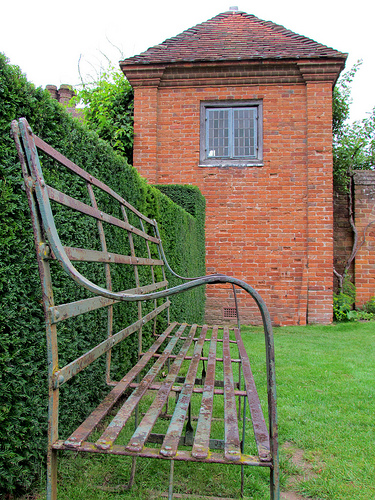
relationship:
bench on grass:
[7, 114, 286, 499] [1, 316, 373, 498]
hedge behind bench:
[1, 178, 208, 489] [22, 133, 308, 488]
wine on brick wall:
[333, 176, 359, 290] [331, 165, 373, 315]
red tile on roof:
[197, 26, 264, 53] [116, 4, 347, 57]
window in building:
[199, 99, 264, 168] [118, 4, 348, 323]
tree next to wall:
[333, 141, 373, 321] [354, 184, 374, 313]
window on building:
[199, 98, 264, 168] [116, 1, 372, 324]